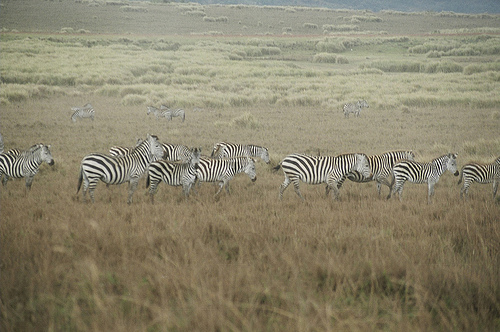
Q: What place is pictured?
A: It is a field.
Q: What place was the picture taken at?
A: It was taken at the field.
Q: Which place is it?
A: It is a field.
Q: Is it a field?
A: Yes, it is a field.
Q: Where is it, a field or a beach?
A: It is a field.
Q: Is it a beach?
A: No, it is a field.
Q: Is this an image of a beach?
A: No, the picture is showing a field.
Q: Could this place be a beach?
A: No, it is a field.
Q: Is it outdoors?
A: Yes, it is outdoors.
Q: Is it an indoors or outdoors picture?
A: It is outdoors.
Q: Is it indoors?
A: No, it is outdoors.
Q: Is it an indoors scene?
A: No, it is outdoors.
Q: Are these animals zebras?
A: Yes, all the animals are zebras.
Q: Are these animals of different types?
A: No, all the animals are zebras.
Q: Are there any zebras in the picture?
A: Yes, there is a zebra.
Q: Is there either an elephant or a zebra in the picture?
A: Yes, there is a zebra.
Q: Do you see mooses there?
A: No, there are no mooses.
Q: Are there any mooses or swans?
A: No, there are no mooses or swans.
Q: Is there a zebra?
A: Yes, there is a zebra.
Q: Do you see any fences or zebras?
A: Yes, there is a zebra.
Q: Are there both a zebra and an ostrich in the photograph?
A: No, there is a zebra but no ostriches.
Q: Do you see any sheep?
A: No, there are no sheep.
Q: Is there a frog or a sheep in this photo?
A: No, there are no sheep or frogs.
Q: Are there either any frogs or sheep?
A: No, there are no sheep or frogs.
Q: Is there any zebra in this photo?
A: Yes, there is a zebra.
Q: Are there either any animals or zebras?
A: Yes, there is a zebra.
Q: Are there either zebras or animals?
A: Yes, there is a zebra.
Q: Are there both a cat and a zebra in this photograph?
A: No, there is a zebra but no cats.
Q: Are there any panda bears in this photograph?
A: No, there are no panda bears.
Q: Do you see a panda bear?
A: No, there are no panda bears.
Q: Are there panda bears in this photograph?
A: No, there are no panda bears.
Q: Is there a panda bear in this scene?
A: No, there are no panda bears.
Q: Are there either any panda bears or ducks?
A: No, there are no panda bears or ducks.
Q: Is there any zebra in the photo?
A: Yes, there is a zebra.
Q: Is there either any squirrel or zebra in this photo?
A: Yes, there is a zebra.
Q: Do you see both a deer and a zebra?
A: No, there is a zebra but no deer.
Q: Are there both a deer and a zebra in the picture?
A: No, there is a zebra but no deer.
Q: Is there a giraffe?
A: No, there are no giraffes.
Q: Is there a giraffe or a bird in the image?
A: No, there are no giraffes or birds.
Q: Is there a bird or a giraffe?
A: No, there are no giraffes or birds.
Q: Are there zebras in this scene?
A: Yes, there is a zebra.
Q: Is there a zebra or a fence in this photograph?
A: Yes, there is a zebra.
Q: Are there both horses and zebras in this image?
A: No, there is a zebra but no horses.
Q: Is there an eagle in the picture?
A: No, there are no eagles.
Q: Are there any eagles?
A: No, there are no eagles.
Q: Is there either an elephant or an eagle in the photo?
A: No, there are no eagles or elephants.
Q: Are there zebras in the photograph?
A: Yes, there are zebras.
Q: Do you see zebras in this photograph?
A: Yes, there are zebras.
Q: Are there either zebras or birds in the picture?
A: Yes, there are zebras.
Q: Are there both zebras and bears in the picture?
A: No, there are zebras but no bears.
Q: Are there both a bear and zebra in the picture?
A: No, there are zebras but no bears.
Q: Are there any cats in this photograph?
A: No, there are no cats.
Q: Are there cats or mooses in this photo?
A: No, there are no cats or mooses.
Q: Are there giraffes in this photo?
A: No, there are no giraffes.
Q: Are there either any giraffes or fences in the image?
A: No, there are no giraffes or fences.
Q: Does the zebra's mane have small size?
A: Yes, the mane is small.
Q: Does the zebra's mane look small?
A: Yes, the mane is small.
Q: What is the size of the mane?
A: The mane is small.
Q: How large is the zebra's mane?
A: The mane is small.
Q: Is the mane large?
A: No, the mane is small.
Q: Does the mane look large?
A: No, the mane is small.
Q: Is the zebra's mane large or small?
A: The mane is small.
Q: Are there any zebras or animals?
A: Yes, there is a zebra.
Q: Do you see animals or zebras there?
A: Yes, there is a zebra.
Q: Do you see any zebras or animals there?
A: Yes, there is a zebra.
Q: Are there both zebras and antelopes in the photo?
A: No, there is a zebra but no antelopes.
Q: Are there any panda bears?
A: No, there are no panda bears.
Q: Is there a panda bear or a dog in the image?
A: No, there are no pandas or dogs.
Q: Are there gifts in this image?
A: No, there are no gifts.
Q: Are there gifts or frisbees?
A: No, there are no gifts or frisbees.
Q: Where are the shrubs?
A: The shrubs are in the field.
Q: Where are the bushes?
A: The shrubs are in the field.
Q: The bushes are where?
A: The bushes are on the field.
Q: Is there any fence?
A: No, there are no fences.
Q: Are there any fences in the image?
A: No, there are no fences.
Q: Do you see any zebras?
A: Yes, there is a zebra.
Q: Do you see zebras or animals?
A: Yes, there is a zebra.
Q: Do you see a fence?
A: No, there are no fences.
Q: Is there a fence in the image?
A: No, there are no fences.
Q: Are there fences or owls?
A: No, there are no fences or owls.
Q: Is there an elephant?
A: No, there are no elephants.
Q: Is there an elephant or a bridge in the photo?
A: No, there are no elephants or bridges.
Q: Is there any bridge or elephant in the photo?
A: No, there are no elephants or bridges.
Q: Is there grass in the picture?
A: Yes, there is grass.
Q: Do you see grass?
A: Yes, there is grass.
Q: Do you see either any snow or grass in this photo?
A: Yes, there is grass.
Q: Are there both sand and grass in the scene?
A: No, there is grass but no sand.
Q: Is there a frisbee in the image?
A: No, there are no frisbees.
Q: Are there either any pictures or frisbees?
A: No, there are no frisbees or pictures.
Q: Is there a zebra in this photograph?
A: Yes, there is a zebra.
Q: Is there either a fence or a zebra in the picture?
A: Yes, there is a zebra.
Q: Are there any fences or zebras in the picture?
A: Yes, there is a zebra.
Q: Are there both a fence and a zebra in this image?
A: No, there is a zebra but no fences.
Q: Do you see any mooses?
A: No, there are no mooses.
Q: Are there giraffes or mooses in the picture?
A: No, there are no mooses or giraffes.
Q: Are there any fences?
A: No, there are no fences.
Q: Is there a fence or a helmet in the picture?
A: No, there are no fences or helmets.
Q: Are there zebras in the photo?
A: Yes, there is a zebra.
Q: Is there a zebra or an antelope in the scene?
A: Yes, there is a zebra.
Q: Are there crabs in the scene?
A: No, there are no crabs.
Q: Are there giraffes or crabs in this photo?
A: No, there are no crabs or giraffes.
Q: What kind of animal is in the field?
A: The animal is a zebra.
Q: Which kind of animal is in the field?
A: The animal is a zebra.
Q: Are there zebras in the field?
A: Yes, there is a zebra in the field.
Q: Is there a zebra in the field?
A: Yes, there is a zebra in the field.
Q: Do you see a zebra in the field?
A: Yes, there is a zebra in the field.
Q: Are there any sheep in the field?
A: No, there is a zebra in the field.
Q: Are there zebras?
A: Yes, there is a zebra.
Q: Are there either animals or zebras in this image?
A: Yes, there is a zebra.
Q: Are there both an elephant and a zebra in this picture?
A: No, there is a zebra but no elephants.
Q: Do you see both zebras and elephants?
A: No, there is a zebra but no elephants.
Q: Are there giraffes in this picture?
A: No, there are no giraffes.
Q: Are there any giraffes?
A: No, there are no giraffes.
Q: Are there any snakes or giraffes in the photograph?
A: No, there are no giraffes or snakes.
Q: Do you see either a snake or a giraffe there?
A: No, there are no giraffes or snakes.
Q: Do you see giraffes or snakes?
A: No, there are no giraffes or snakes.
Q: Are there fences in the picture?
A: No, there are no fences.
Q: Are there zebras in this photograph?
A: Yes, there is a zebra.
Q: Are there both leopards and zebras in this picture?
A: No, there is a zebra but no leopards.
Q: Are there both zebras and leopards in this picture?
A: No, there is a zebra but no leopards.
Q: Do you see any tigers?
A: No, there are no tigers.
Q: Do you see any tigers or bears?
A: No, there are no tigers or bears.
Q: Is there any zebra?
A: Yes, there is a zebra.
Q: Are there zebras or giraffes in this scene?
A: Yes, there is a zebra.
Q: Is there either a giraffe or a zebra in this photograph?
A: Yes, there is a zebra.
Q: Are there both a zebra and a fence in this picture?
A: No, there is a zebra but no fences.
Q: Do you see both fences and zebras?
A: No, there is a zebra but no fences.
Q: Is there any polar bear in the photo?
A: No, there are no polar bears.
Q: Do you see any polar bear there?
A: No, there are no polar bears.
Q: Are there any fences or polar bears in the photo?
A: No, there are no polar bears or fences.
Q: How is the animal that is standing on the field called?
A: The animal is a zebra.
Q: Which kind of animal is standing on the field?
A: The animal is a zebra.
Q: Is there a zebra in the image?
A: Yes, there is a zebra.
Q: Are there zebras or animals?
A: Yes, there is a zebra.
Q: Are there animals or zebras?
A: Yes, there is a zebra.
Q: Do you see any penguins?
A: No, there are no penguins.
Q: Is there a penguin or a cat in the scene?
A: No, there are no penguins or cats.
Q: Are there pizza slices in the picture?
A: No, there are no pizza slices.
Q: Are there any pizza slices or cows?
A: No, there are no pizza slices or cows.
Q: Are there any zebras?
A: Yes, there is a zebra.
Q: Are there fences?
A: No, there are no fences.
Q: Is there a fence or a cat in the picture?
A: No, there are no fences or cats.